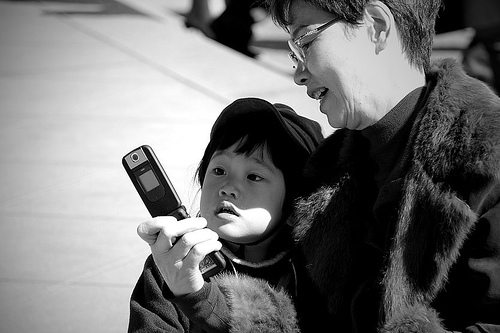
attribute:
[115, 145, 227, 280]
cellphone — present, plastic, black, silver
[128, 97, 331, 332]
girl — young, little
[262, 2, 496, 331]
lady — smiling, asian, talking, explaining, earringless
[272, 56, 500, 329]
coat — fur, dark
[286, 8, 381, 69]
glasses — black, round, wire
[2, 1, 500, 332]
photo — black, white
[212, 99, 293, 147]
brim — black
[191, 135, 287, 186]
hair — shaggy